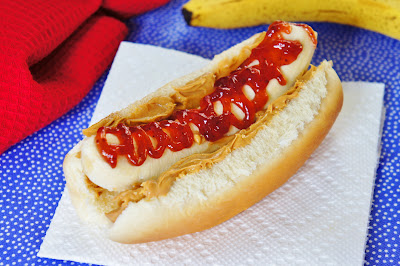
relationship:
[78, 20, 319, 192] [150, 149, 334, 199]
banana in bun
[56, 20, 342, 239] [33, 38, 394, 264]
hotdog sandwich on napkin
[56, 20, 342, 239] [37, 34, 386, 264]
hotdog sandwich on towel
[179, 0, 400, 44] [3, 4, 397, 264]
banana on table cloth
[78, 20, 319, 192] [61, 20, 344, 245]
banana in a hotdog bun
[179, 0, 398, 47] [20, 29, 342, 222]
banana on table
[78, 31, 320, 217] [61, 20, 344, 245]
peanut butter on bun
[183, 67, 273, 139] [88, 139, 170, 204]
jelly on banana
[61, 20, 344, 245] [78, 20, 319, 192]
bun under banana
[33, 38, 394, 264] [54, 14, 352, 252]
napkin under food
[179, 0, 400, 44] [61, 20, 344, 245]
banana on bun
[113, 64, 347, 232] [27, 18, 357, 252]
bun on napkin